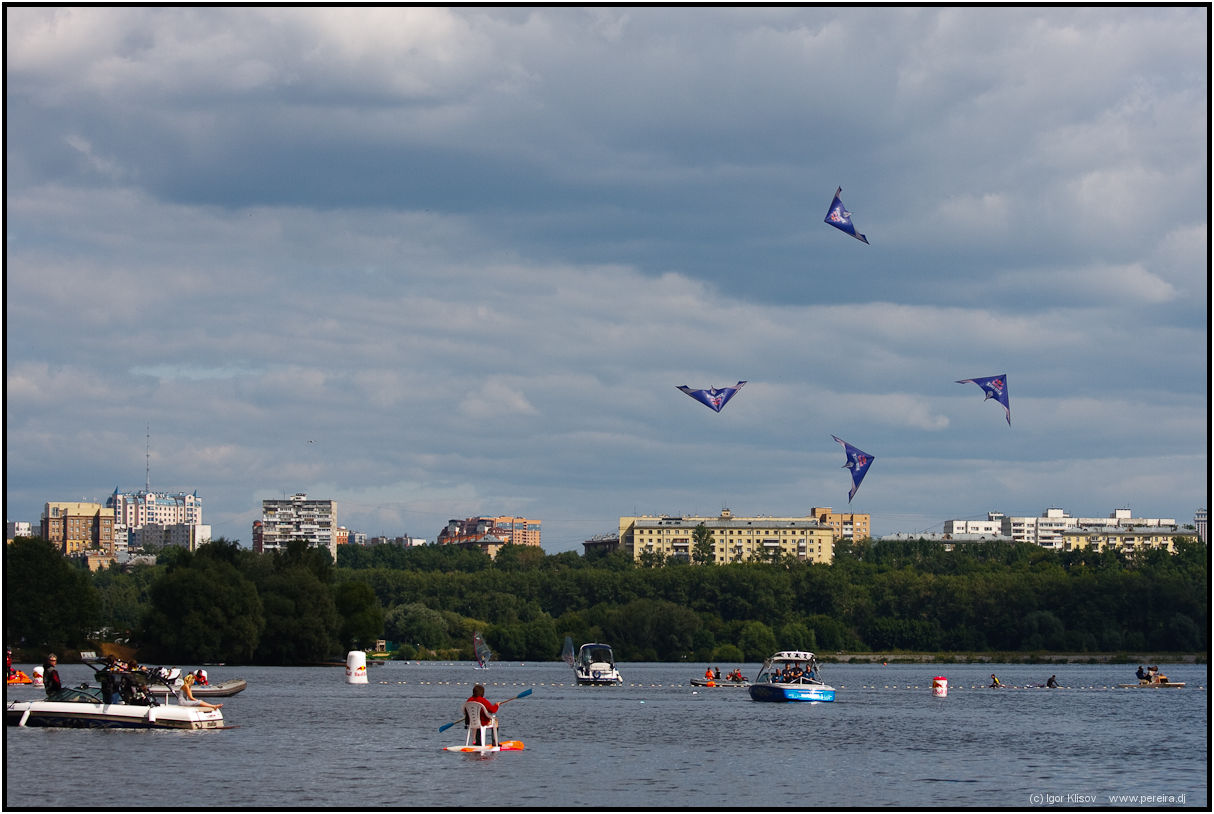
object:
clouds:
[0, 0, 1214, 560]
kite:
[829, 435, 876, 506]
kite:
[954, 373, 1012, 428]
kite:
[674, 381, 747, 414]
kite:
[824, 184, 871, 245]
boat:
[747, 650, 837, 703]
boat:
[560, 636, 624, 686]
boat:
[73, 674, 249, 697]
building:
[252, 492, 338, 565]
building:
[39, 501, 114, 556]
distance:
[0, 452, 1214, 573]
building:
[437, 515, 542, 560]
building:
[106, 420, 201, 551]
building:
[943, 508, 1175, 553]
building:
[618, 507, 835, 570]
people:
[439, 635, 1169, 749]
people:
[0, 647, 1186, 758]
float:
[439, 740, 525, 753]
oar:
[439, 688, 534, 734]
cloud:
[0, 0, 469, 98]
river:
[4, 661, 1212, 813]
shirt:
[463, 695, 497, 729]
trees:
[0, 536, 1208, 664]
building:
[943, 520, 1001, 534]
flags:
[674, 184, 1008, 503]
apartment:
[252, 492, 338, 565]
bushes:
[347, 590, 560, 661]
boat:
[441, 740, 525, 756]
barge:
[0, 686, 243, 730]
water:
[0, 644, 1208, 814]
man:
[463, 685, 500, 748]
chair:
[461, 701, 498, 747]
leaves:
[482, 569, 560, 663]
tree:
[482, 590, 562, 658]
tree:
[609, 522, 714, 625]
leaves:
[633, 549, 691, 569]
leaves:
[605, 595, 695, 663]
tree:
[626, 599, 716, 664]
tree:
[712, 621, 818, 664]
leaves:
[727, 619, 781, 663]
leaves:
[779, 569, 874, 653]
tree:
[738, 538, 872, 661]